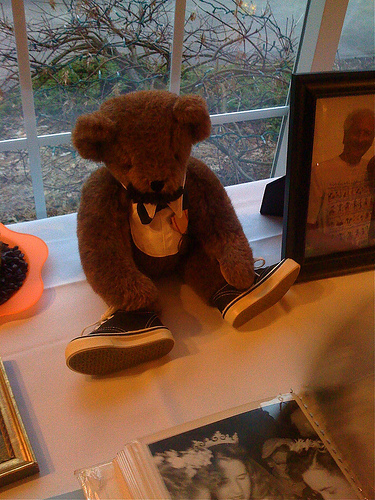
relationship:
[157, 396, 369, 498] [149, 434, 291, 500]
photo of lady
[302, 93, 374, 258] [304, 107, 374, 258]
photo of man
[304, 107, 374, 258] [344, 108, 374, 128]
man with gray hair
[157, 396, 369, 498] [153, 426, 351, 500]
photo of women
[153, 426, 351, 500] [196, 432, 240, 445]
women wearing tiara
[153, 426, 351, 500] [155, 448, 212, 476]
women wearing flowers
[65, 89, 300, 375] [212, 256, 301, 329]
bear wearing shoes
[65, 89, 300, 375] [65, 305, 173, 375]
bear wearing shoes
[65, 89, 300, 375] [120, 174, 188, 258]
bear wearing bib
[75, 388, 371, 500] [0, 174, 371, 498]
album on table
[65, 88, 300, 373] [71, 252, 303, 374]
bear wearing shoes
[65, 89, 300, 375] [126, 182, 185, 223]
bear wearing bowtie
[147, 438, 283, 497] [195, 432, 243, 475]
lady wearing tiara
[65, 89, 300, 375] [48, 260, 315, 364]
bear wearing shoes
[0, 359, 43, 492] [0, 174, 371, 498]
picture frame on table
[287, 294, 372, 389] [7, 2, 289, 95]
tabletop near window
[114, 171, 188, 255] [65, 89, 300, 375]
bib on bear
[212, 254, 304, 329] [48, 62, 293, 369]
shoes of bear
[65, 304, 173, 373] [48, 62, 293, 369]
shoes of bear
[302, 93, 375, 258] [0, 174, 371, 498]
photo on table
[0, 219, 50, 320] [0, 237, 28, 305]
bowl filled with stones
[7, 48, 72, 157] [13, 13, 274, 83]
framing of window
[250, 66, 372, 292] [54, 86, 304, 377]
frame next to teddy bear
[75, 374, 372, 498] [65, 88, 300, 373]
album in front of bear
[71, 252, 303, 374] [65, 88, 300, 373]
shoes on bear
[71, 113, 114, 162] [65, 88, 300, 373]
ear on bear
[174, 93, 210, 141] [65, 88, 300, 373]
ear on bear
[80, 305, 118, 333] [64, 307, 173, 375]
laces on shoe